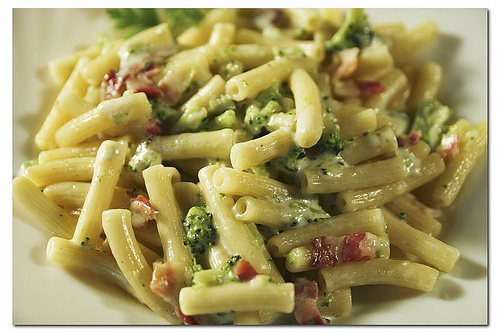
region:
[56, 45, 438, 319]
plate of maccoroni salad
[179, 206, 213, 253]
small piece of broccoli in pasta salad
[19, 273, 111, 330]
white plate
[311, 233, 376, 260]
small piece of bacon in pasta salad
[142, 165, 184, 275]
small pasta noodle in pasta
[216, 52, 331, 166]
pasta noodles and broccoli in sauce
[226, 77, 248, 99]
open end of piece of pasta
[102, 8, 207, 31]
piece of parsley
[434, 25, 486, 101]
shadow on the plate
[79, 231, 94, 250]
tiny fleck from a piece of broccoli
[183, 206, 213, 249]
A small piece of broccoli.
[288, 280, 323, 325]
A minute piece of bacon.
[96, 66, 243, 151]
A mix of bacon and broccoli.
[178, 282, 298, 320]
An oily tube shaped noodle.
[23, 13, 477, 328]
A serving of pasta.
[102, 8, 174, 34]
A blurry piece of parsley.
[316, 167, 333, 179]
A small fleck of pepper.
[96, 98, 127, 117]
A gob of clear liquid on the noodle.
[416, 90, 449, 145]
A large broccoli stem.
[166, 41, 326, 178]
Several noodles, mixed with peppered broccoli.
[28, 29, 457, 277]
food on a plate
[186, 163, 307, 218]
noodles are a yellow color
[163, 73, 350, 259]
little pieces of broccoli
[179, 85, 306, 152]
the brocolli is green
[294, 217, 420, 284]
pieces of bacon mixed in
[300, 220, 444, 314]
the bacon is red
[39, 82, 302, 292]
noodles in the food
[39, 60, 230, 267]
the noodles are yellow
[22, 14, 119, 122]
the plate is white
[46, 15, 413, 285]
food mixed together on plate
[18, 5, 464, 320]
a noodle dish on a white plate.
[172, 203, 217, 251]
a piece of broccoli on a plate.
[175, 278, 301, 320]
a piece of pasta on a plate.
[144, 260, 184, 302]
a piece of bacon on a plate.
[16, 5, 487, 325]
A white plate of food.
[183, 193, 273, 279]
broccoli on a pasta dish.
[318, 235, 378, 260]
a piece of food on other food.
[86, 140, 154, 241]
a noodle covered in sauce.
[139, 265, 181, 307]
a sauce covered piece of bacon.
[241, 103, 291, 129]
sauce covered broccoli.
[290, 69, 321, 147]
A cooked noodle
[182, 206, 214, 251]
A piece of broccoli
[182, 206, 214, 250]
A cooked piece of broccoli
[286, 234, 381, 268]
A noodle covered in sauce and pork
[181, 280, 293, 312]
Cooked noodle on a plate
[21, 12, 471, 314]
Cooked ziti on a plate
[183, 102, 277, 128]
Chunks of broccoli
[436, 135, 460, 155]
A piece of meat on a plate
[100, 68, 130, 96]
A piece of pork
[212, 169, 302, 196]
A freshly cooked noodle